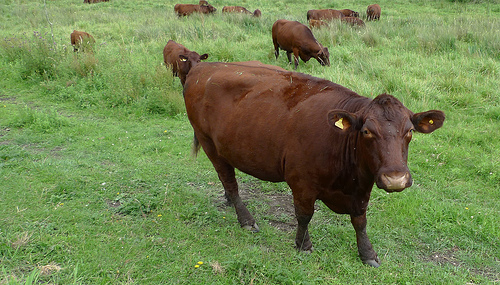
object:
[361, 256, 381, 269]
pedals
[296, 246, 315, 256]
pedals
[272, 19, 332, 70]
cow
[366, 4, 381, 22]
cow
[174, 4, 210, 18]
cow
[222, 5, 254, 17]
cow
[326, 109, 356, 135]
ear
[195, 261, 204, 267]
flower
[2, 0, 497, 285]
green grass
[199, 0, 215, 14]
cows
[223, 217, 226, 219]
yellow flowers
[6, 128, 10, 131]
dirt track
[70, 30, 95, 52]
cow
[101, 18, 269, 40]
grass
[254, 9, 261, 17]
cows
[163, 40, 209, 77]
cow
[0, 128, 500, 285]
path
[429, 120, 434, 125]
tags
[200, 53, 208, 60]
ears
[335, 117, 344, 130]
tab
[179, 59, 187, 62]
tab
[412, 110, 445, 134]
ear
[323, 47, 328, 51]
ear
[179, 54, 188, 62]
ear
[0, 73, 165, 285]
grass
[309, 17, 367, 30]
cow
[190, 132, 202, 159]
tail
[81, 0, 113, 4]
cows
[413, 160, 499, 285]
grass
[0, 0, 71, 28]
grass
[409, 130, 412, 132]
eye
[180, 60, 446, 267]
cow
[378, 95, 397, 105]
tuft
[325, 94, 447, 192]
head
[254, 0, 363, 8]
grass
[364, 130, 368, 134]
eye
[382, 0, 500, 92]
grass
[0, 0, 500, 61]
background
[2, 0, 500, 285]
field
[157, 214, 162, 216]
flowers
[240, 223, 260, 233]
hoof